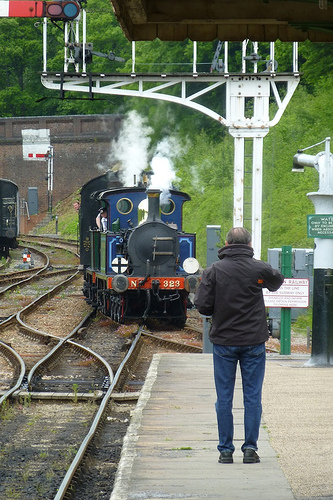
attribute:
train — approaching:
[78, 171, 197, 327]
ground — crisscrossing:
[2, 234, 279, 499]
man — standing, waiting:
[194, 228, 286, 465]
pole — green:
[277, 247, 294, 356]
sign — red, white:
[260, 278, 311, 308]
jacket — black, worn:
[192, 244, 286, 349]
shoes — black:
[217, 448, 261, 464]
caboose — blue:
[79, 174, 151, 301]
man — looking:
[72, 200, 81, 214]